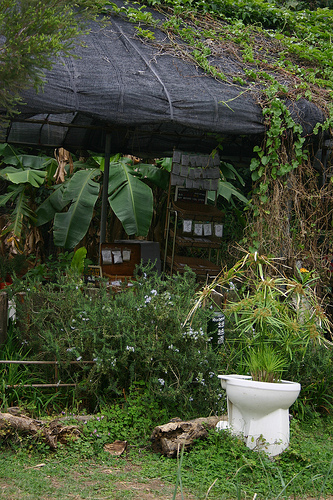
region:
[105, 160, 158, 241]
Giant green banana leaf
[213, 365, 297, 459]
White toilet seat on the grass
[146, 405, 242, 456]
Part of the tree trunk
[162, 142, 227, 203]
Many papers in shade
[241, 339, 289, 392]
Grass sprouting forth from toilet seat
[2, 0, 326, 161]
Rooftop covering the house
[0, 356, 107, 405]
Metal rails in the thick jungle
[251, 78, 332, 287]
Overgrown wild brown roots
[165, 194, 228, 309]
Wooden stand with papers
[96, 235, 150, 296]
Brown suitcase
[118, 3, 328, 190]
Ivy growing on a black roof.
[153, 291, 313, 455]
White porcelain toilet with plants in the bowl.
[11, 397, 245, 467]
Wooden logs on the ground.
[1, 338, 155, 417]
Metal fence surrounded by vegetation.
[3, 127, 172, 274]
Large flat leaves.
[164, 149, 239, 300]
Wicker baskets on a metal rack.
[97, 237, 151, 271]
Small white signs enclosed in plastic.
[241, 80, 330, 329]
Long vines with green leaves.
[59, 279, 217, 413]
Plants with small white leaves.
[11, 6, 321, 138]
Black cloth roof.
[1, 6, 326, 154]
the umbrella above everything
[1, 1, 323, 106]
the plants growing on the umbrella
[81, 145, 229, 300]
the shelves under the umbrella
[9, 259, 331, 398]
the plants next to the shelves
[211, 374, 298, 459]
the toilet holding a plant in it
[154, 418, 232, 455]
the tree next to the toilet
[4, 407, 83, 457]
another tree on the ground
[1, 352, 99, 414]
a fence along the plants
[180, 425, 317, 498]
grass on the ground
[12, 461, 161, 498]
some dirt on the ground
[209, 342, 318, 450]
old toilet with plant in bowl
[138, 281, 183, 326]
white wild flower in the weeds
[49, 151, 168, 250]
large green tree leaves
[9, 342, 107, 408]
fence in the weeds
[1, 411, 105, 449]
log on the ground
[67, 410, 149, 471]
stump by a log and weeds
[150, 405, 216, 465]
log on the ground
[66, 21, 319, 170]
entrance to a cave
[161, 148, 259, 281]
sign in front a cave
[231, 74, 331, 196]
vines hanging over entrance to a cave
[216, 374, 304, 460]
the toilet is white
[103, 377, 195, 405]
the grass is green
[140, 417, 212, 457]
the log is rotten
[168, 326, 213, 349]
the flowers are white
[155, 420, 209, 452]
the log is grey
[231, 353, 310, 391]
the grass is growing in the toilet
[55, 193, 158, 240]
the banana leaves are green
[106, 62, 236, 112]
the roof is grey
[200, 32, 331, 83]
there are green leaves on the roof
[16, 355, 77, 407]
the bars are mettalic